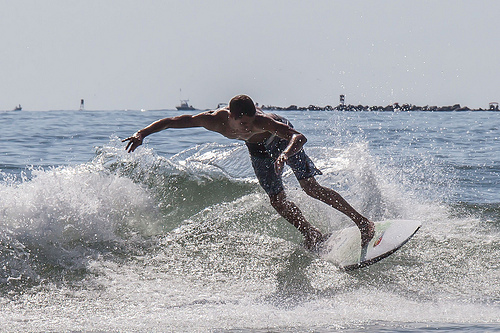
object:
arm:
[121, 112, 206, 154]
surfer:
[120, 93, 375, 247]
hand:
[121, 130, 143, 154]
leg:
[269, 202, 323, 251]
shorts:
[245, 116, 323, 197]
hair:
[227, 93, 256, 120]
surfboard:
[289, 219, 422, 272]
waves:
[32, 167, 251, 275]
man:
[121, 94, 376, 251]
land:
[298, 88, 500, 128]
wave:
[0, 176, 171, 277]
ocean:
[0, 109, 211, 289]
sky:
[0, 0, 500, 91]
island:
[261, 92, 499, 121]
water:
[325, 108, 499, 174]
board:
[300, 219, 424, 271]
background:
[0, 0, 500, 141]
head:
[226, 94, 257, 133]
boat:
[12, 104, 23, 111]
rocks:
[393, 103, 469, 113]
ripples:
[26, 120, 98, 157]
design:
[372, 232, 384, 249]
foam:
[330, 133, 399, 186]